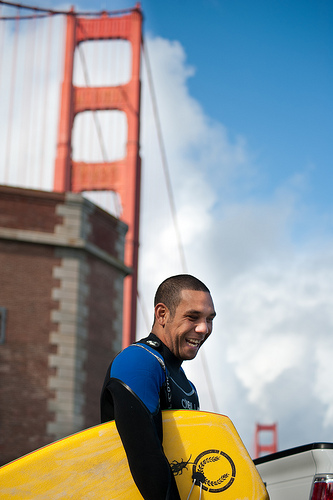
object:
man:
[99, 274, 216, 411]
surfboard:
[0, 410, 271, 499]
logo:
[191, 448, 235, 492]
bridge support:
[58, 8, 142, 194]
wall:
[2, 190, 135, 458]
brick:
[25, 257, 49, 269]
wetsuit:
[99, 346, 212, 422]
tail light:
[310, 475, 333, 499]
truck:
[251, 443, 333, 499]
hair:
[154, 281, 179, 304]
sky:
[151, 0, 332, 267]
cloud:
[228, 249, 333, 400]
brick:
[22, 318, 48, 336]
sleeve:
[113, 350, 180, 500]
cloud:
[178, 130, 236, 267]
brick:
[91, 320, 103, 328]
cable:
[143, 42, 163, 163]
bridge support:
[255, 424, 277, 453]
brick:
[95, 361, 109, 370]